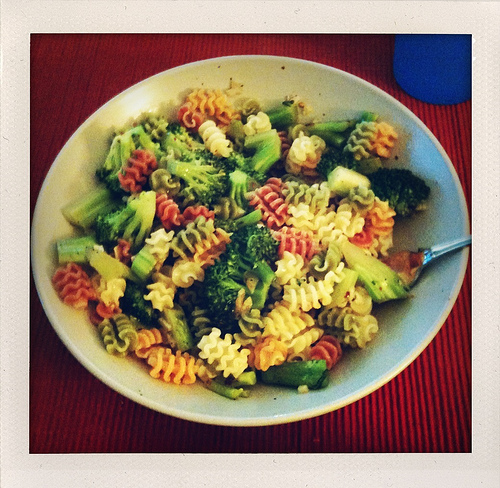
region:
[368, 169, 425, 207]
piece of broccoli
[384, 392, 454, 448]
striped red placemat under the plate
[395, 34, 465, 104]
blue cup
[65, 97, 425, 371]
white bowl of broccoli and pasta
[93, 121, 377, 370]
multicolored pasta and broccoli in a bowl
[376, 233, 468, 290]
fork in the bowl of food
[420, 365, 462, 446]
red stripes under the plate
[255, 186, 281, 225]
red pasta noodle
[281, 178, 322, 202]
green pasta noodle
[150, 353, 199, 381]
orange pasta noodle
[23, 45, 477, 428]
a round white bowl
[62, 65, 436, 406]
a bowl of food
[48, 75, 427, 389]
pasta and veggies in a bowl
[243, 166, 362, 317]
white orange and green pasta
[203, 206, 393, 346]
chunks of broccoli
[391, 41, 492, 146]
a blue cup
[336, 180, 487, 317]
a part of a utensil sticking out of bowl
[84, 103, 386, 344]
pasta mixed with broccoli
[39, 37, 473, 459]
a red placemat under bowl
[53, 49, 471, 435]
a round white bowl of food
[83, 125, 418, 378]
The pasta is multi colored.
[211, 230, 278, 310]
Broccoli is in the bowl.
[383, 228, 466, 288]
The fork is in the bowl.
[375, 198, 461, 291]
The fork is silver.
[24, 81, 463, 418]
The bowl is white.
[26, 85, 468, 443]
The bowl is on the table.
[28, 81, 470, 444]
The table is red.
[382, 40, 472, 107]
The cup is blue.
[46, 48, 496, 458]
The cup is next to the bowl.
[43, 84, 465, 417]
The noodles are in the bowl.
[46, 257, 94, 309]
peice of pasta on a plate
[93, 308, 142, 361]
peice of pasta on a plate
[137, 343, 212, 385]
peice of pasta on a plate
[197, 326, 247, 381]
peice of pasta on a plate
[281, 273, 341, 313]
peice of pasta on a plate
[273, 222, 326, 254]
peice of pasta on a plate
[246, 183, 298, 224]
peice of pasta on a plate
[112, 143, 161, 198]
peice of pasta on a plate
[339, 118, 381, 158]
peice of pasta on a plate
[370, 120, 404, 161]
peice of pasta on a plate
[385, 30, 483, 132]
a dark blue cup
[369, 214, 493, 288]
a silver utensil in bowl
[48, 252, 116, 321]
an orange piece of pasta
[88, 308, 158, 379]
a green piece of pasta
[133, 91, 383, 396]
several chunks of broccoli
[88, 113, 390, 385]
broccoli and pasta mixture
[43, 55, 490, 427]
a bowl full of food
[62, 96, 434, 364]
broccoli and pasta in a bowl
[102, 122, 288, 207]
dark green broccoli chunks